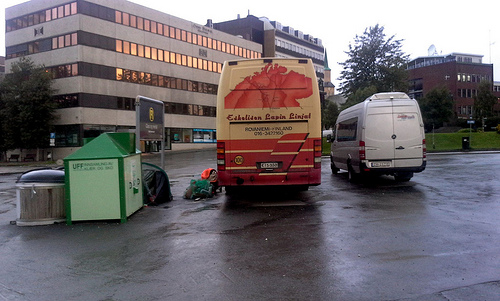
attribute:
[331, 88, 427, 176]
van — white, small, parked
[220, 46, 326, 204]
bus — tan, red, big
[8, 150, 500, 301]
parking lot — wet, asphalt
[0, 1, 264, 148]
building — large, red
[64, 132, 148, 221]
trash bin — green, small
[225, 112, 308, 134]
writing — red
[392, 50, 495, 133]
building — brick, red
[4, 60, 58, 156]
tree — green, large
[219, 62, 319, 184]
back — tan, red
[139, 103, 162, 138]
sign — black, yellow, brown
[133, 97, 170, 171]
poles — metal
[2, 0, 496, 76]
clouds — white, overcast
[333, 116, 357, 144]
windows — dark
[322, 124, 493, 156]
grass — green, short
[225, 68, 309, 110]
design — red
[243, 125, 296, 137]
text — black